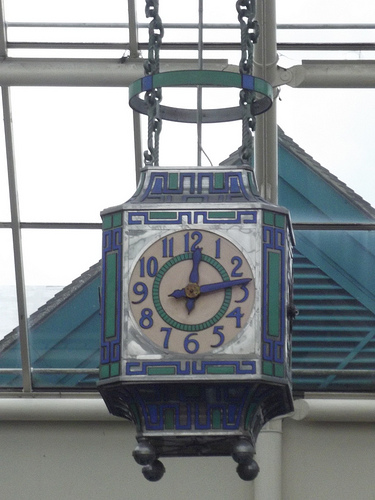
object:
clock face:
[122, 209, 262, 381]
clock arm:
[168, 278, 253, 299]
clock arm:
[186, 245, 203, 316]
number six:
[183, 333, 199, 355]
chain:
[235, 0, 257, 167]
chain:
[143, 0, 164, 167]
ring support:
[129, 69, 274, 123]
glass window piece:
[9, 86, 136, 223]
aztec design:
[95, 167, 296, 482]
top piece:
[217, 125, 317, 167]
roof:
[0, 0, 374, 398]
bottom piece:
[95, 373, 295, 417]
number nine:
[132, 282, 148, 305]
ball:
[231, 440, 256, 464]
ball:
[236, 459, 260, 481]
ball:
[142, 459, 166, 481]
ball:
[132, 443, 156, 465]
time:
[128, 229, 255, 354]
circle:
[152, 252, 232, 332]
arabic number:
[184, 231, 203, 252]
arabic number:
[162, 237, 174, 257]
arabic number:
[231, 256, 243, 277]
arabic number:
[139, 307, 153, 328]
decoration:
[131, 171, 266, 204]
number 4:
[226, 306, 244, 328]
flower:
[185, 282, 201, 299]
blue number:
[215, 238, 221, 258]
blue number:
[140, 256, 158, 277]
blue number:
[160, 327, 173, 349]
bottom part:
[95, 375, 296, 483]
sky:
[0, 0, 375, 346]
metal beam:
[0, 56, 375, 90]